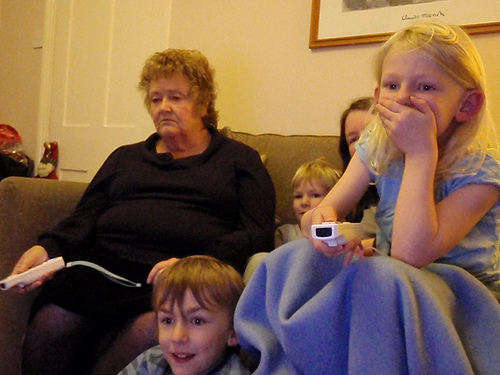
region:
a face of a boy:
[151, 304, 212, 368]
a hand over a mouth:
[367, 91, 445, 148]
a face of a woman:
[148, 83, 187, 134]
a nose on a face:
[154, 96, 176, 117]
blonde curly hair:
[136, 48, 211, 85]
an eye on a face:
[410, 74, 442, 99]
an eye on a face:
[341, 126, 363, 150]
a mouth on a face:
[167, 350, 196, 364]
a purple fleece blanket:
[359, 266, 444, 351]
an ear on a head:
[453, 87, 485, 130]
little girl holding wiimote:
[276, 32, 498, 362]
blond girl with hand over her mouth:
[348, 23, 498, 265]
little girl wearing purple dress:
[235, 16, 498, 373]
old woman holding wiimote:
[5, 52, 292, 374]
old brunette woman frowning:
[128, 50, 228, 157]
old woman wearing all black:
[2, 37, 284, 372]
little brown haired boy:
[113, 245, 256, 372]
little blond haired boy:
[285, 157, 346, 230]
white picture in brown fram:
[308, 1, 498, 48]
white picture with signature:
[309, 0, 498, 49]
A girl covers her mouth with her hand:
[311, 22, 476, 297]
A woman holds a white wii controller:
[18, 32, 253, 324]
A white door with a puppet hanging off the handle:
[32, 6, 182, 203]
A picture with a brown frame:
[306, 0, 494, 57]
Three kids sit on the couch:
[99, 35, 484, 366]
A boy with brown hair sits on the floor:
[110, 252, 282, 373]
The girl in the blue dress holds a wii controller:
[303, 27, 481, 324]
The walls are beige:
[197, 17, 337, 118]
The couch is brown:
[181, 93, 343, 205]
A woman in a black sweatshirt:
[72, 38, 246, 258]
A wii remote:
[303, 216, 348, 253]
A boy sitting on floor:
[137, 244, 240, 374]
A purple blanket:
[232, 226, 495, 373]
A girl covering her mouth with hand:
[297, 2, 498, 279]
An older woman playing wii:
[12, 12, 244, 373]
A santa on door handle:
[27, 126, 54, 197]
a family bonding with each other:
[3, 21, 498, 373]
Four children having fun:
[132, 22, 492, 372]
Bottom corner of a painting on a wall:
[293, 0, 496, 52]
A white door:
[40, 2, 183, 184]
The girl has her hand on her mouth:
[352, 57, 499, 187]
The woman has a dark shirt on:
[121, 75, 257, 275]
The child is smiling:
[132, 268, 231, 366]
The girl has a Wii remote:
[300, 222, 393, 304]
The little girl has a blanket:
[260, 225, 490, 371]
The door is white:
[20, 15, 258, 165]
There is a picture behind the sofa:
[292, 0, 495, 70]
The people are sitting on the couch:
[17, 134, 460, 369]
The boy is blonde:
[125, 242, 235, 369]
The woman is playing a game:
[3, 237, 133, 374]